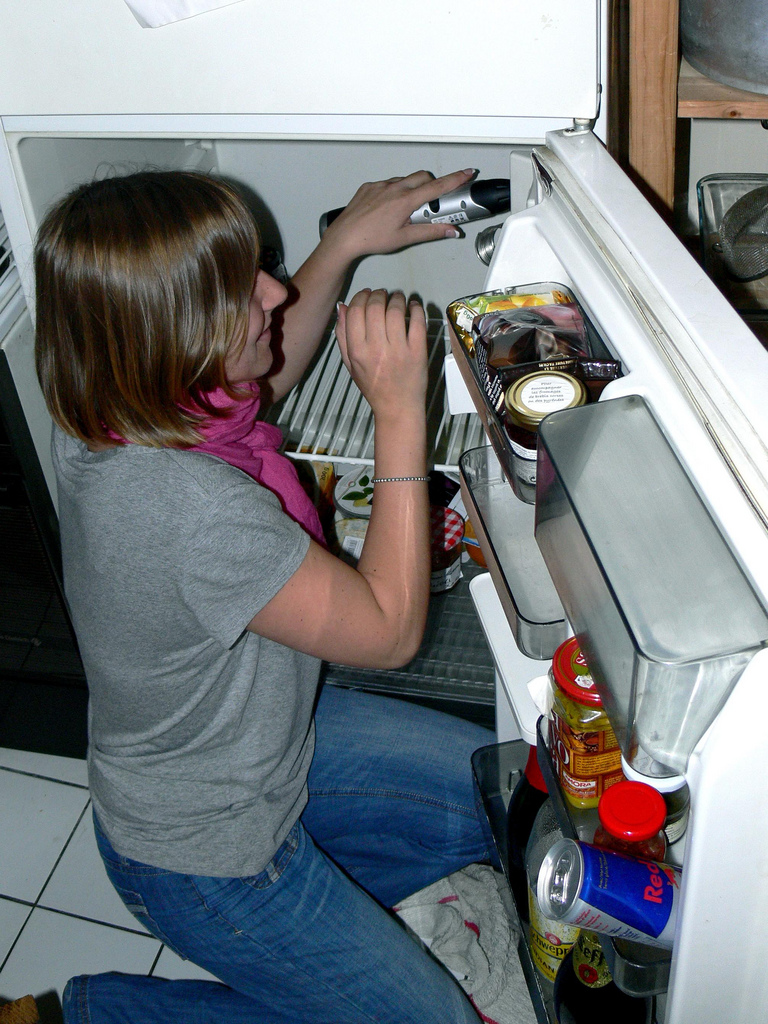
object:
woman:
[35, 161, 476, 1023]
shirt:
[51, 444, 326, 876]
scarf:
[96, 364, 328, 558]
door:
[445, 123, 766, 1023]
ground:
[0, 747, 223, 1023]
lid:
[597, 781, 666, 842]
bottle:
[536, 838, 681, 951]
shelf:
[533, 395, 768, 776]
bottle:
[593, 780, 667, 862]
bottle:
[548, 636, 630, 816]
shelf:
[469, 570, 691, 1021]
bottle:
[554, 929, 657, 1024]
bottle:
[526, 799, 585, 1005]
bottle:
[505, 370, 587, 487]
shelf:
[445, 280, 623, 505]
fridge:
[0, 0, 768, 1021]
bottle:
[333, 465, 376, 519]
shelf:
[294, 466, 520, 710]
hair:
[39, 161, 260, 449]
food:
[430, 506, 465, 594]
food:
[450, 291, 621, 502]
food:
[505, 635, 691, 1024]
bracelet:
[371, 477, 430, 482]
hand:
[343, 169, 474, 256]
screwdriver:
[319, 178, 510, 241]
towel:
[393, 862, 532, 1023]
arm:
[176, 416, 431, 671]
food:
[273, 435, 377, 565]